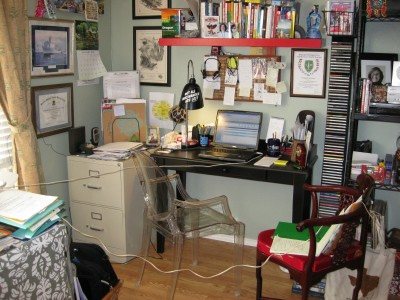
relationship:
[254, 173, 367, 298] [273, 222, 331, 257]
chair covered with notebooks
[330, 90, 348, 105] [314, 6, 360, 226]
cd stacked in column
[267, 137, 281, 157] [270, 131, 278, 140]
cup holding pencils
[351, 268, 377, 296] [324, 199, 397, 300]
texas emblam on bag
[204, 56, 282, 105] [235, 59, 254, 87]
bulletin board covered with paper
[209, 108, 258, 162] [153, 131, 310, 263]
laptop on desk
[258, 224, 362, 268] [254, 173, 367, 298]
seat on chair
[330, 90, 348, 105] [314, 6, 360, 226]
cd in column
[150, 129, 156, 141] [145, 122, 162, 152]
photo in frame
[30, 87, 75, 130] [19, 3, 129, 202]
diploma hanging on wall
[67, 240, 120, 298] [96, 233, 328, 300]
backpack on floor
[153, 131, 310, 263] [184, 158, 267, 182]
desk has drawer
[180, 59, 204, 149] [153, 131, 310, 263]
lamp on desk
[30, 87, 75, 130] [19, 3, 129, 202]
diploma on wall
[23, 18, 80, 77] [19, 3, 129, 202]
picture on wall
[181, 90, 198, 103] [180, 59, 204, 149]
letters on lamp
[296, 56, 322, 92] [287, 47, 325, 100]
certificate in frame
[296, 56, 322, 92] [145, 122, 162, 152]
certificate in frame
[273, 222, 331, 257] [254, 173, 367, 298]
notebooks on chair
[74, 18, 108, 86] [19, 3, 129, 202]
calendar on wall